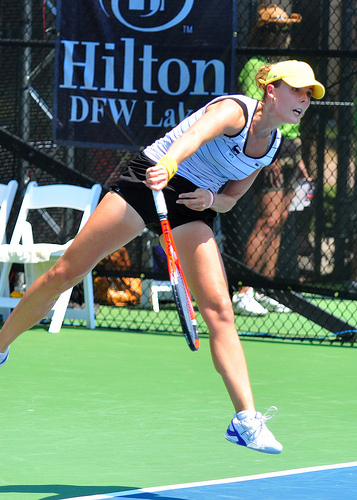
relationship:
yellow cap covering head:
[248, 46, 343, 114] [261, 59, 314, 126]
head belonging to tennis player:
[261, 59, 314, 126] [0, 57, 327, 455]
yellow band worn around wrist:
[147, 148, 184, 186] [159, 155, 179, 180]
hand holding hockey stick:
[141, 162, 170, 191] [151, 182, 201, 353]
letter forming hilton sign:
[59, 38, 100, 91] [58, 35, 230, 98]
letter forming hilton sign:
[98, 40, 118, 91] [58, 35, 230, 98]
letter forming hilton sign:
[119, 35, 137, 92] [58, 35, 230, 98]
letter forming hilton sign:
[137, 42, 159, 93] [58, 35, 230, 98]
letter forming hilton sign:
[157, 57, 192, 96] [58, 35, 230, 98]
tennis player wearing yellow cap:
[0, 59, 327, 456] [229, 49, 336, 127]